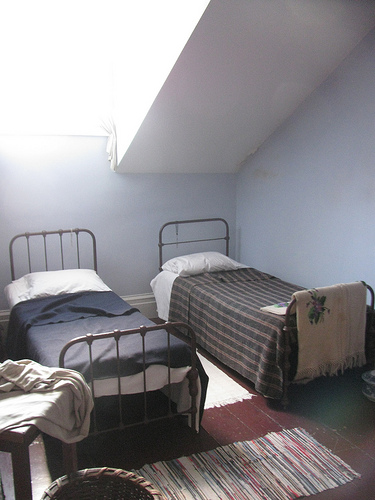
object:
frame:
[8, 226, 97, 281]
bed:
[8, 226, 200, 474]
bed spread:
[166, 267, 309, 401]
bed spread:
[4, 288, 209, 433]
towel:
[258, 281, 367, 387]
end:
[292, 350, 368, 385]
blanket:
[260, 280, 367, 384]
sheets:
[148, 272, 171, 312]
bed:
[148, 218, 374, 412]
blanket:
[7, 289, 210, 431]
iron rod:
[58, 228, 65, 270]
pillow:
[12, 268, 110, 302]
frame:
[58, 332, 95, 370]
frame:
[279, 280, 375, 411]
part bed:
[213, 278, 245, 292]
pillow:
[160, 251, 240, 278]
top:
[158, 86, 209, 162]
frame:
[158, 217, 230, 272]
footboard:
[58, 321, 198, 439]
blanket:
[0, 358, 94, 445]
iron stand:
[186, 367, 199, 440]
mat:
[129, 426, 361, 498]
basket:
[40, 465, 164, 499]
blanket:
[168, 267, 370, 402]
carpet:
[128, 426, 362, 500]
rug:
[195, 349, 258, 410]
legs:
[4, 427, 63, 499]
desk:
[0, 369, 80, 498]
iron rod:
[86, 339, 98, 433]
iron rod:
[113, 332, 124, 427]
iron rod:
[140, 325, 148, 422]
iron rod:
[165, 327, 171, 417]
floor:
[206, 399, 375, 500]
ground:
[0, 409, 375, 500]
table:
[0, 378, 63, 500]